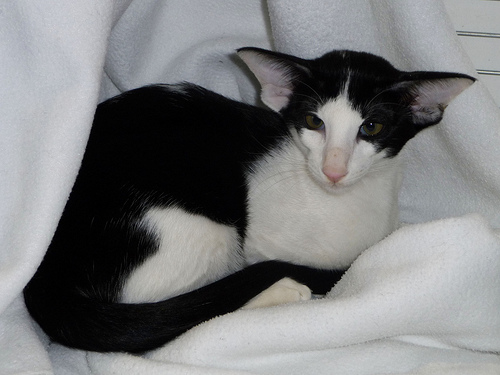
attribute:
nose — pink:
[315, 159, 358, 188]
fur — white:
[259, 157, 316, 265]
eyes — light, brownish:
[295, 110, 401, 151]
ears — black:
[236, 37, 468, 136]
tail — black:
[63, 250, 333, 348]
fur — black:
[113, 115, 231, 166]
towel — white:
[309, 220, 499, 343]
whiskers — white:
[241, 137, 322, 224]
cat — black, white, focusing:
[31, 18, 469, 342]